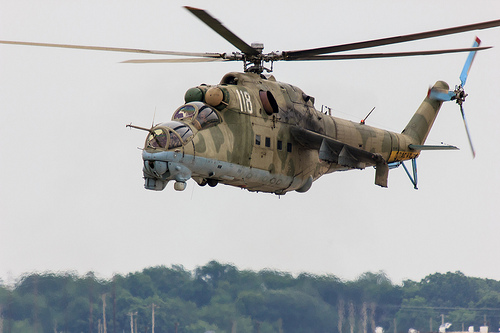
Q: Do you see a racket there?
A: No, there are no rackets.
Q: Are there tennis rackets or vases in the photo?
A: No, there are no tennis rackets or vases.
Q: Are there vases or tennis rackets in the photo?
A: No, there are no tennis rackets or vases.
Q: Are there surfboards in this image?
A: No, there are no surfboards.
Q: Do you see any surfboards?
A: No, there are no surfboards.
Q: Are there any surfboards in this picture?
A: No, there are no surfboards.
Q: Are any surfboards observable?
A: No, there are no surfboards.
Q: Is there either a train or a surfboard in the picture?
A: No, there are no surfboards or trains.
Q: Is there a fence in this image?
A: No, there are no fences.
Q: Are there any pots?
A: No, there are no pots.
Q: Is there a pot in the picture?
A: No, there are no pots.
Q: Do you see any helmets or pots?
A: No, there are no pots or helmets.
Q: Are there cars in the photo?
A: No, there are no cars.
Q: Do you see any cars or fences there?
A: No, there are no cars or fences.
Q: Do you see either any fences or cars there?
A: No, there are no cars or fences.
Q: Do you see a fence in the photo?
A: No, there are no fences.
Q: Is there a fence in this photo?
A: No, there are no fences.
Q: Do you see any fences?
A: No, there are no fences.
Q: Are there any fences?
A: No, there are no fences.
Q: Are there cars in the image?
A: No, there are no cars.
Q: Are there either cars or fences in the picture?
A: No, there are no cars or fences.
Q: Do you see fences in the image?
A: No, there are no fences.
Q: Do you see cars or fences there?
A: No, there are no fences or cars.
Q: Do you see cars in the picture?
A: No, there are no cars.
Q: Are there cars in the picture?
A: No, there are no cars.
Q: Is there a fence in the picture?
A: No, there are no fences.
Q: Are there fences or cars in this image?
A: No, there are no fences or cars.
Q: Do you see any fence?
A: No, there are no fences.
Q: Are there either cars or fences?
A: No, there are no fences or cars.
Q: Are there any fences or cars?
A: No, there are no fences or cars.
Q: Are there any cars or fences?
A: No, there are no cars or fences.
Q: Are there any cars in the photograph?
A: No, there are no cars.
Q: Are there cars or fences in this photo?
A: No, there are no cars or fences.